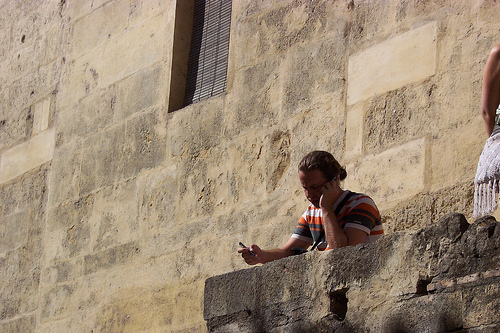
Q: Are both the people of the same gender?
A: No, they are both male and female.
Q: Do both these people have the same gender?
A: No, they are both male and female.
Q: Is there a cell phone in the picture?
A: Yes, there is a cell phone.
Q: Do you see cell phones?
A: Yes, there is a cell phone.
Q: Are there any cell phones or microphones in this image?
A: Yes, there is a cell phone.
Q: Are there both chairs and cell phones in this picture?
A: No, there is a cell phone but no chairs.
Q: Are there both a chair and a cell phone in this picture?
A: No, there is a cell phone but no chairs.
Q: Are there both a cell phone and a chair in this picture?
A: No, there is a cell phone but no chairs.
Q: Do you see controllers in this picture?
A: No, there are no controllers.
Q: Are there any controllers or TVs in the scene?
A: No, there are no controllers or tvs.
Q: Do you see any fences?
A: No, there are no fences.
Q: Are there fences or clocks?
A: No, there are no fences or clocks.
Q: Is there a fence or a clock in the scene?
A: No, there are no fences or clocks.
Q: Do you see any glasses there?
A: No, there are no glasses.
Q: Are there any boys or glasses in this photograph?
A: No, there are no glasses or boys.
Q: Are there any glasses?
A: No, there are no glasses.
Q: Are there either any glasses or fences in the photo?
A: No, there are no glasses or fences.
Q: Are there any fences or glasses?
A: No, there are no glasses or fences.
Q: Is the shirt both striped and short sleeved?
A: Yes, the shirt is striped and short sleeved.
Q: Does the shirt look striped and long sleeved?
A: No, the shirt is striped but short sleeved.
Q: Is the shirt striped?
A: Yes, the shirt is striped.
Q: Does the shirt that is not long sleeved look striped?
A: Yes, the shirt is striped.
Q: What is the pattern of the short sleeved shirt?
A: The shirt is striped.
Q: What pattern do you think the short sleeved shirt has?
A: The shirt has striped pattern.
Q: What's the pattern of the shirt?
A: The shirt is striped.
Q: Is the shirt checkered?
A: No, the shirt is striped.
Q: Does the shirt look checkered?
A: No, the shirt is striped.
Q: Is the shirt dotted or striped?
A: The shirt is striped.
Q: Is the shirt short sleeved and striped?
A: Yes, the shirt is short sleeved and striped.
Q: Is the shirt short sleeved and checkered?
A: No, the shirt is short sleeved but striped.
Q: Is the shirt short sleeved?
A: Yes, the shirt is short sleeved.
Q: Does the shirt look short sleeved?
A: Yes, the shirt is short sleeved.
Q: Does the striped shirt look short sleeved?
A: Yes, the shirt is short sleeved.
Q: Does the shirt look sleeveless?
A: No, the shirt is short sleeved.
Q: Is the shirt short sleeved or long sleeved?
A: The shirt is short sleeved.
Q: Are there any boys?
A: No, there are no boys.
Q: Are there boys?
A: No, there are no boys.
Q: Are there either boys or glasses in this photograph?
A: No, there are no boys or glasses.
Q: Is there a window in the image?
A: Yes, there is a window.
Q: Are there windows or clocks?
A: Yes, there is a window.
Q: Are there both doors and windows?
A: No, there is a window but no doors.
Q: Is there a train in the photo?
A: No, there are no trains.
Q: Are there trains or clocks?
A: No, there are no trains or clocks.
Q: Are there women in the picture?
A: Yes, there is a woman.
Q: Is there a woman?
A: Yes, there is a woman.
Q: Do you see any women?
A: Yes, there is a woman.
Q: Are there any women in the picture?
A: Yes, there is a woman.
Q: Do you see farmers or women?
A: Yes, there is a woman.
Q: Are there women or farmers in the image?
A: Yes, there is a woman.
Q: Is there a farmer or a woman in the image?
A: Yes, there is a woman.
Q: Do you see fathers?
A: No, there are no fathers.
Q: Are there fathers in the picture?
A: No, there are no fathers.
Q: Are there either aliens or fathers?
A: No, there are no fathers or aliens.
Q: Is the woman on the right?
A: Yes, the woman is on the right of the image.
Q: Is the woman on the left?
A: No, the woman is on the right of the image.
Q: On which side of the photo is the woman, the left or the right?
A: The woman is on the right of the image.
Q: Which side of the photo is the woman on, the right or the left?
A: The woman is on the right of the image.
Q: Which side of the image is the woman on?
A: The woman is on the right of the image.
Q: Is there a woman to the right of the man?
A: Yes, there is a woman to the right of the man.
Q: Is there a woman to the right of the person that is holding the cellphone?
A: Yes, there is a woman to the right of the man.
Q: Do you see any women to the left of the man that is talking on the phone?
A: No, the woman is to the right of the man.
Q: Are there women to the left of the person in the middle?
A: No, the woman is to the right of the man.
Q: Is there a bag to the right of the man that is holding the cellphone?
A: No, there is a woman to the right of the man.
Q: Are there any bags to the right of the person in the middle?
A: No, there is a woman to the right of the man.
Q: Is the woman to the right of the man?
A: Yes, the woman is to the right of the man.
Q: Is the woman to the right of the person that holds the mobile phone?
A: Yes, the woman is to the right of the man.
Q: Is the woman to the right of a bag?
A: No, the woman is to the right of the man.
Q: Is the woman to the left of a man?
A: No, the woman is to the right of a man.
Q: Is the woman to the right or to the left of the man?
A: The woman is to the right of the man.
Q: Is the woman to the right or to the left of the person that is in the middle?
A: The woman is to the right of the man.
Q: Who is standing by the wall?
A: The woman is standing by the wall.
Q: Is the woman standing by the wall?
A: Yes, the woman is standing by the wall.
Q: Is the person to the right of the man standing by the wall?
A: Yes, the woman is standing by the wall.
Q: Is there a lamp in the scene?
A: No, there are no lamps.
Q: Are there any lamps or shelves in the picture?
A: No, there are no lamps or shelves.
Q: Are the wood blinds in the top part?
A: Yes, the blinds are in the top of the image.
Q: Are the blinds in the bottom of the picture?
A: No, the blinds are in the top of the image.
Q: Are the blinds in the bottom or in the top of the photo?
A: The blinds are in the top of the image.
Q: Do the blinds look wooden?
A: Yes, the blinds are wooden.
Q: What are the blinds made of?
A: The blinds are made of wood.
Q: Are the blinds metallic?
A: No, the blinds are wooden.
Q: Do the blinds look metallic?
A: No, the blinds are wooden.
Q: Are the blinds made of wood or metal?
A: The blinds are made of wood.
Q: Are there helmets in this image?
A: No, there are no helmets.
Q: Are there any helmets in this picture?
A: No, there are no helmets.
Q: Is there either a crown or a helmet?
A: No, there are no helmets or crowns.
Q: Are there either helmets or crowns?
A: No, there are no helmets or crowns.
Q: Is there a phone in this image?
A: Yes, there is a phone.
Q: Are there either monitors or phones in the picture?
A: Yes, there is a phone.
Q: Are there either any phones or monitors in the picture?
A: Yes, there is a phone.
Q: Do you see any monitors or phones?
A: Yes, there is a phone.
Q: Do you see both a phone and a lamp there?
A: No, there is a phone but no lamps.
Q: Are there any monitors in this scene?
A: No, there are no monitors.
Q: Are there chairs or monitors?
A: No, there are no monitors or chairs.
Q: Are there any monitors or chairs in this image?
A: No, there are no monitors or chairs.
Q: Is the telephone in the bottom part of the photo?
A: Yes, the telephone is in the bottom of the image.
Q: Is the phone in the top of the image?
A: No, the phone is in the bottom of the image.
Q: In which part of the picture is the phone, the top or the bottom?
A: The phone is in the bottom of the image.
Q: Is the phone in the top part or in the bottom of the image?
A: The phone is in the bottom of the image.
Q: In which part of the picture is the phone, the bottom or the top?
A: The phone is in the bottom of the image.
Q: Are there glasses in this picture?
A: No, there are no glasses.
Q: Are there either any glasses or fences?
A: No, there are no glasses or fences.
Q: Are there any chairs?
A: No, there are no chairs.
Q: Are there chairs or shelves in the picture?
A: No, there are no chairs or shelves.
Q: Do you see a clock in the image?
A: No, there are no clocks.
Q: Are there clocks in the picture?
A: No, there are no clocks.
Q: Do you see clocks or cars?
A: No, there are no clocks or cars.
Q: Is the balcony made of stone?
A: Yes, the balcony is made of stone.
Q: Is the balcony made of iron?
A: No, the balcony is made of stone.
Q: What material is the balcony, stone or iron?
A: The balcony is made of stone.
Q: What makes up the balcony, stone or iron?
A: The balcony is made of stone.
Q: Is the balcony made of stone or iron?
A: The balcony is made of stone.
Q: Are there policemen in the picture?
A: No, there are no policemen.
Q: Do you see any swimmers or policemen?
A: No, there are no policemen or swimmers.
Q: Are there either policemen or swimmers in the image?
A: No, there are no policemen or swimmers.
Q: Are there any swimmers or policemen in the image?
A: No, there are no policemen or swimmers.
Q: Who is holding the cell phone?
A: The man is holding the cell phone.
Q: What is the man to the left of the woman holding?
A: The man is holding the mobile phone.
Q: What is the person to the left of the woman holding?
A: The man is holding the mobile phone.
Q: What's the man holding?
A: The man is holding the mobile phone.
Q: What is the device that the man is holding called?
A: The device is a cell phone.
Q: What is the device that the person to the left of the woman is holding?
A: The device is a cell phone.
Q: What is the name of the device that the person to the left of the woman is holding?
A: The device is a cell phone.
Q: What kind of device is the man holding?
A: The man is holding the mobile phone.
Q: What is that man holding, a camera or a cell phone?
A: The man is holding a cell phone.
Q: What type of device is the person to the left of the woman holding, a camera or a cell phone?
A: The man is holding a cell phone.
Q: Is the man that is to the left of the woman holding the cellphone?
A: Yes, the man is holding the cellphone.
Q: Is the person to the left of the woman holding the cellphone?
A: Yes, the man is holding the cellphone.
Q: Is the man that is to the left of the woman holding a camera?
A: No, the man is holding the cellphone.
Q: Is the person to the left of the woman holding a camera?
A: No, the man is holding the cellphone.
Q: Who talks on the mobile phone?
A: The man talks on the mobile phone.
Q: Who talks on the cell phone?
A: The man talks on the mobile phone.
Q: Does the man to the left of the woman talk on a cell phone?
A: Yes, the man talks on a cell phone.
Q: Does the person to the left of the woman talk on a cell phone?
A: Yes, the man talks on a cell phone.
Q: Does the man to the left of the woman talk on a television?
A: No, the man talks on a cell phone.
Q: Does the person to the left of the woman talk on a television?
A: No, the man talks on a cell phone.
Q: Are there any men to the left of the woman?
A: Yes, there is a man to the left of the woman.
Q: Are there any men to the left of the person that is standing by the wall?
A: Yes, there is a man to the left of the woman.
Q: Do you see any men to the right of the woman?
A: No, the man is to the left of the woman.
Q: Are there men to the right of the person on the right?
A: No, the man is to the left of the woman.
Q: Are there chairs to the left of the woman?
A: No, there is a man to the left of the woman.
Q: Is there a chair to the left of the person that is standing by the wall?
A: No, there is a man to the left of the woman.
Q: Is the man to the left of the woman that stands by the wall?
A: Yes, the man is to the left of the woman.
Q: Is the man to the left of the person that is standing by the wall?
A: Yes, the man is to the left of the woman.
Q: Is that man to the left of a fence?
A: No, the man is to the left of the woman.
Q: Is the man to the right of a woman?
A: No, the man is to the left of a woman.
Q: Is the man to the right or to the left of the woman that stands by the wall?
A: The man is to the left of the woman.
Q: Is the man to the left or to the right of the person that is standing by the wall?
A: The man is to the left of the woman.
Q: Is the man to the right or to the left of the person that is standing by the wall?
A: The man is to the left of the woman.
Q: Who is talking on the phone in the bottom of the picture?
A: The man is talking on the telephone.